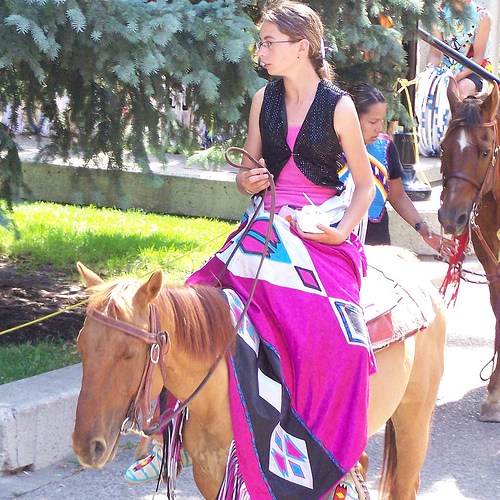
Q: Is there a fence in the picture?
A: No, there are no fences.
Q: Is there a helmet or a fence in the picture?
A: No, there are no fences or helmets.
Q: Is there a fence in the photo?
A: No, there are no fences.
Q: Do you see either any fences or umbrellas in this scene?
A: No, there are no fences or umbrellas.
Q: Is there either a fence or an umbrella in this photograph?
A: No, there are no fences or umbrellas.